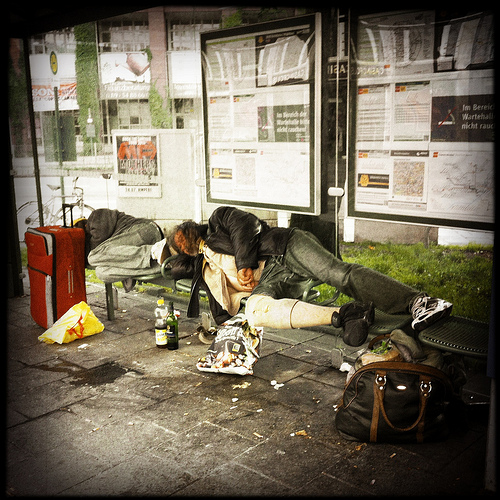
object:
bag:
[334, 361, 468, 445]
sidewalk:
[0, 268, 500, 500]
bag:
[37, 301, 105, 346]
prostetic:
[245, 294, 339, 329]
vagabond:
[160, 206, 452, 348]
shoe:
[332, 300, 377, 347]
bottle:
[167, 302, 178, 350]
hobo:
[73, 208, 169, 284]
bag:
[24, 225, 88, 330]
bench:
[419, 310, 500, 362]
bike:
[15, 175, 95, 242]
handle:
[375, 385, 429, 432]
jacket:
[171, 206, 292, 325]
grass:
[313, 238, 494, 323]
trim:
[370, 383, 380, 442]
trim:
[43, 235, 56, 329]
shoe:
[409, 294, 453, 331]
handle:
[62, 203, 75, 228]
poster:
[199, 29, 324, 215]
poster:
[350, 6, 500, 233]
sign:
[114, 128, 164, 200]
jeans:
[248, 227, 419, 316]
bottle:
[154, 299, 169, 349]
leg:
[245, 264, 375, 347]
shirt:
[199, 239, 266, 316]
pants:
[87, 221, 162, 284]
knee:
[244, 293, 271, 328]